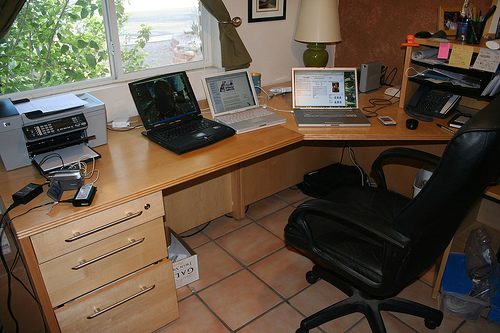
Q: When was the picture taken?
A: During the day.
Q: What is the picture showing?
A: A desk.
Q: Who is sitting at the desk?
A: No one.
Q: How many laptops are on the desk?
A: Three.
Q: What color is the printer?
A: Gray.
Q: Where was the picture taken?
A: In a home office.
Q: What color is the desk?
A: Natural.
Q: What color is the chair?
A: Black.